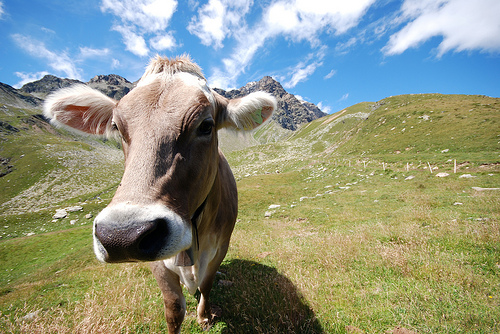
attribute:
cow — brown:
[39, 52, 287, 331]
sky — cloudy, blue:
[1, 1, 500, 106]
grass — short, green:
[1, 141, 500, 331]